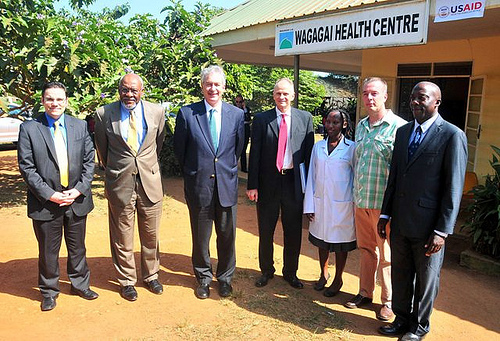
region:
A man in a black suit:
[10, 65, 106, 306]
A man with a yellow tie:
[12, 71, 98, 311]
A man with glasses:
[15, 70, 100, 310]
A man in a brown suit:
[85, 60, 182, 306]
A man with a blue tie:
[171, 55, 251, 295]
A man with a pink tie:
[245, 70, 310, 295]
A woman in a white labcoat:
[296, 102, 361, 297]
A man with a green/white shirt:
[345, 66, 405, 316]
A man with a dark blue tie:
[370, 66, 471, 336]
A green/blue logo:
[267, 20, 297, 51]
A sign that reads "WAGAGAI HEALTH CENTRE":
[270, 2, 430, 56]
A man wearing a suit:
[372, 76, 472, 338]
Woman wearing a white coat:
[300, 104, 360, 297]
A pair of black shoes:
[192, 275, 237, 306]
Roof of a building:
[195, 0, 379, 39]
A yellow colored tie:
[49, 120, 74, 191]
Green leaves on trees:
[1, 1, 324, 129]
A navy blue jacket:
[168, 98, 250, 210]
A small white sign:
[431, 2, 487, 23]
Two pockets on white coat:
[307, 191, 352, 228]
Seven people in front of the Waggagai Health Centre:
[16, 64, 469, 338]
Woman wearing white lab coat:
[302, 104, 357, 297]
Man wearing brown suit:
[91, 71, 175, 300]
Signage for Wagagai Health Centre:
[272, 0, 432, 55]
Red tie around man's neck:
[276, 108, 286, 173]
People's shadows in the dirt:
[0, 248, 390, 336]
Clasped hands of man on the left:
[47, 184, 79, 209]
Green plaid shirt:
[351, 109, 401, 211]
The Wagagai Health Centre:
[199, 0, 497, 276]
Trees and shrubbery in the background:
[0, 0, 365, 138]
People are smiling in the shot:
[16, 45, 458, 146]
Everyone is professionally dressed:
[4, 38, 460, 339]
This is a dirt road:
[81, 303, 317, 339]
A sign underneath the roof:
[260, 2, 496, 67]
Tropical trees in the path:
[3, 2, 328, 142]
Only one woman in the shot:
[298, 100, 366, 302]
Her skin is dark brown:
[302, 100, 366, 303]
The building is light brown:
[356, 42, 494, 264]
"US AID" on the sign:
[436, 2, 491, 31]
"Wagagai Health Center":
[265, 8, 425, 62]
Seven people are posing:
[13, 60, 472, 340]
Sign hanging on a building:
[271, 3, 431, 58]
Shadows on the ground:
[1, 252, 395, 337]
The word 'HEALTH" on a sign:
[331, 18, 373, 43]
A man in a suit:
[16, 79, 101, 312]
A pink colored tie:
[270, 106, 293, 173]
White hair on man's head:
[193, 63, 230, 106]